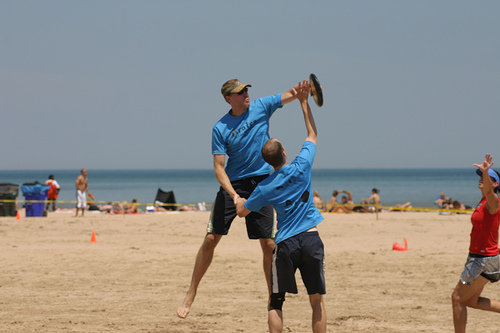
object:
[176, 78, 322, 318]
man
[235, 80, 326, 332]
man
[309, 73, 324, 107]
frisbee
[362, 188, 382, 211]
woman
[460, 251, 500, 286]
shorts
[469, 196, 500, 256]
shirt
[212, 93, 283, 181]
t shirt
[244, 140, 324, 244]
t shirt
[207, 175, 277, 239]
shorts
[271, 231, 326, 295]
shorts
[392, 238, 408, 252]
cone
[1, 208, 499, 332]
beach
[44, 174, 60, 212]
person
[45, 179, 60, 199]
shirt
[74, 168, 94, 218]
guy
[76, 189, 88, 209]
pants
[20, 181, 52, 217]
recycle bin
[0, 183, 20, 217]
trash bin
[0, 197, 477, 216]
crossing tape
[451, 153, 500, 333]
woman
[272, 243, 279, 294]
stripe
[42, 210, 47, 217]
wheel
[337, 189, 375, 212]
guy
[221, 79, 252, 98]
hat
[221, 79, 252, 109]
head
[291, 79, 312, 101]
hand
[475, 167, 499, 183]
visor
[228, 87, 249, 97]
sunglasses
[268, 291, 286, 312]
knee brace